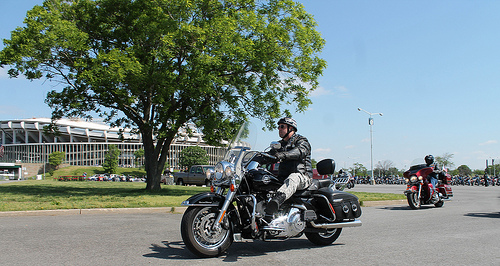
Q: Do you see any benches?
A: No, there are no benches.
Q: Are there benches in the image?
A: No, there are no benches.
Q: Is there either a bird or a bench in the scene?
A: No, there are no benches or birds.